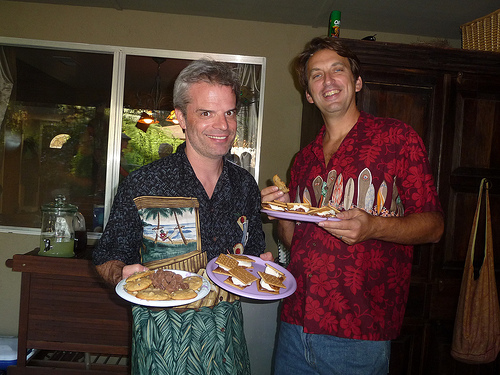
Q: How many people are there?
A: Two.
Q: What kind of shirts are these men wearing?
A: Hawaiian.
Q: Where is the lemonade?
A: Behind the man in the blue shirt.